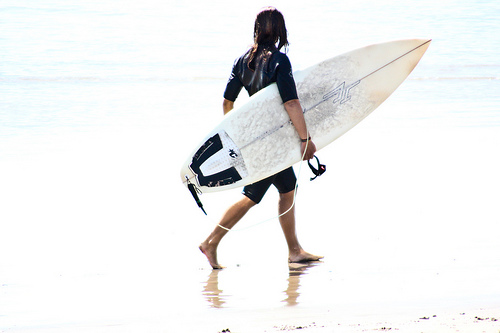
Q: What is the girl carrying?
A: A surfboard.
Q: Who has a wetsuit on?
A: The surfer.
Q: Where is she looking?
A: At the ocean.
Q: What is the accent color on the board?
A: Blue.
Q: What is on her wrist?
A: A band.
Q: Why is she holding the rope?
A: So it doesn't drag.